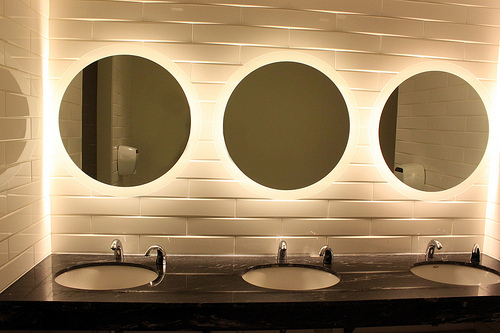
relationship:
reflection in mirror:
[59, 55, 190, 186] [55, 53, 192, 190]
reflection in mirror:
[378, 68, 486, 194] [377, 69, 488, 191]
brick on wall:
[90, 19, 193, 43] [47, 0, 499, 257]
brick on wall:
[189, 23, 288, 50] [47, 0, 499, 257]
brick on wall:
[288, 30, 385, 56] [47, 0, 499, 257]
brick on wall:
[382, 36, 464, 59] [47, 0, 499, 257]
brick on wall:
[234, 198, 329, 218] [47, 0, 499, 257]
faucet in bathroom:
[111, 241, 125, 259] [4, 0, 499, 332]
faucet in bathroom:
[277, 239, 288, 262] [4, 0, 499, 332]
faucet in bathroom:
[420, 238, 442, 262] [4, 0, 499, 332]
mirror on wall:
[55, 53, 192, 190] [47, 0, 499, 257]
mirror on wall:
[221, 60, 351, 198] [47, 0, 499, 257]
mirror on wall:
[377, 69, 488, 191] [47, 0, 499, 257]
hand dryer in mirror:
[116, 144, 138, 176] [55, 53, 192, 190]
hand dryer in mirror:
[395, 160, 425, 186] [377, 69, 488, 191]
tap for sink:
[274, 236, 289, 266] [249, 262, 343, 292]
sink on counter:
[52, 261, 158, 291] [18, 201, 487, 326]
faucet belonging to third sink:
[420, 238, 442, 262] [407, 249, 497, 299]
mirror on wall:
[377, 69, 488, 191] [169, 3, 484, 65]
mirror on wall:
[221, 60, 351, 198] [169, 3, 484, 65]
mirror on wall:
[55, 53, 192, 190] [169, 3, 484, 65]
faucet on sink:
[277, 239, 288, 262] [242, 263, 340, 289]